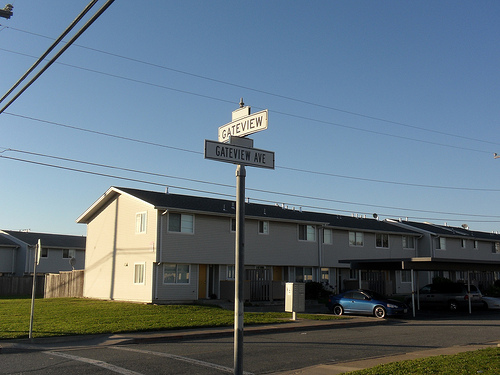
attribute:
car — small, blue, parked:
[327, 285, 404, 314]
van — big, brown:
[404, 283, 484, 306]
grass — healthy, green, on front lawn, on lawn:
[1, 297, 319, 340]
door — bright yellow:
[201, 265, 211, 300]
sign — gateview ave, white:
[205, 141, 276, 170]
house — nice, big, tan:
[82, 195, 499, 323]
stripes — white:
[48, 339, 256, 375]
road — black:
[1, 320, 498, 373]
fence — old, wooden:
[4, 270, 83, 300]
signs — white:
[202, 98, 275, 171]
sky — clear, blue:
[3, 1, 498, 182]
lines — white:
[50, 346, 218, 373]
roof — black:
[114, 187, 409, 231]